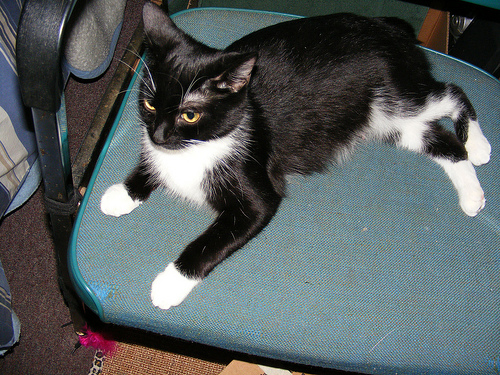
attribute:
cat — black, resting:
[116, 14, 455, 222]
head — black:
[130, 26, 222, 150]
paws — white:
[93, 182, 198, 323]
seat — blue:
[89, 13, 497, 358]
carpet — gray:
[10, 215, 59, 374]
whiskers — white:
[120, 49, 204, 131]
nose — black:
[150, 124, 170, 149]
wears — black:
[140, 10, 261, 84]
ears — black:
[135, 10, 260, 104]